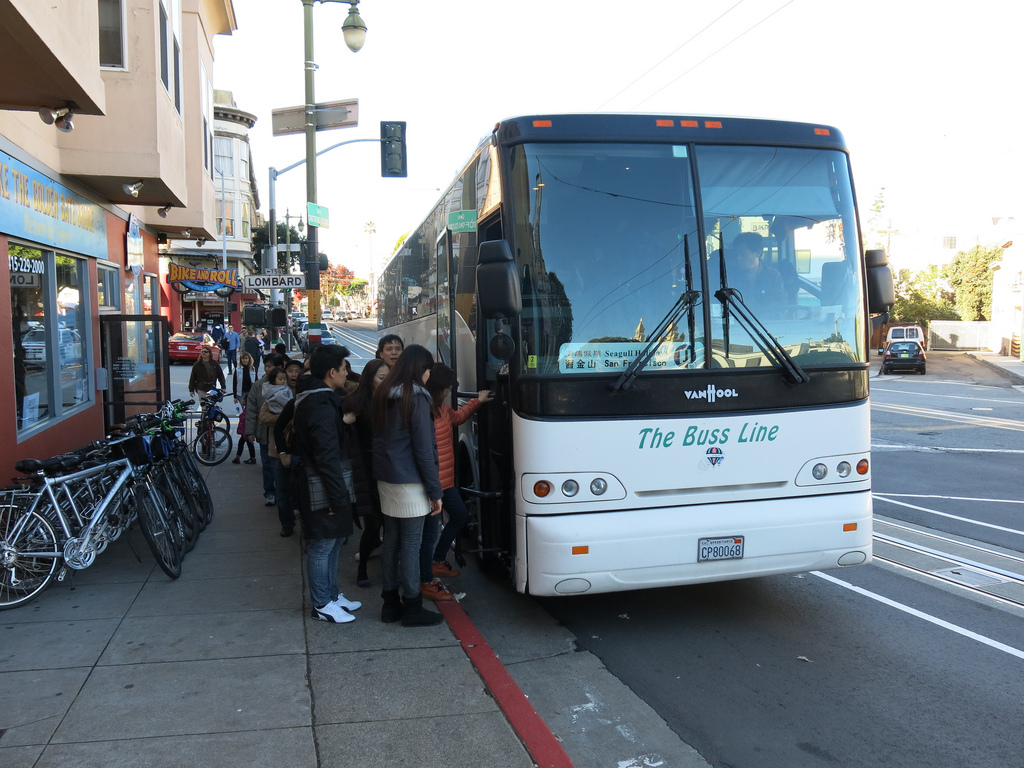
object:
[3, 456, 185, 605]
bicycles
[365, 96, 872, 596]
bus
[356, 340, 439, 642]
passengers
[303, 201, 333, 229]
sign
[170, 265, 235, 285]
sign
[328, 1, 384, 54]
lamp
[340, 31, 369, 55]
bulb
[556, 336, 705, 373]
sign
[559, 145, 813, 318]
window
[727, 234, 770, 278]
driver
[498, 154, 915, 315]
windshield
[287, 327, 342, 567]
person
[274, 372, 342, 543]
jacket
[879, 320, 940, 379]
vehicles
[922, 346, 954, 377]
driveway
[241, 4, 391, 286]
light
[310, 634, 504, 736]
sidewalk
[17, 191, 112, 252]
sign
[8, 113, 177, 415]
building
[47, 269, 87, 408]
window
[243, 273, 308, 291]
sign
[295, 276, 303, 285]
letters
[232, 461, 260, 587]
sidewalk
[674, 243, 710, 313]
seat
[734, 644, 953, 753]
road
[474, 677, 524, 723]
line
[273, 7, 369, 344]
pole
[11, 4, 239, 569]
store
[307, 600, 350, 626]
shoes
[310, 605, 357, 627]
feet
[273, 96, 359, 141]
sign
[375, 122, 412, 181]
sign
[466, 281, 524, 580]
doors